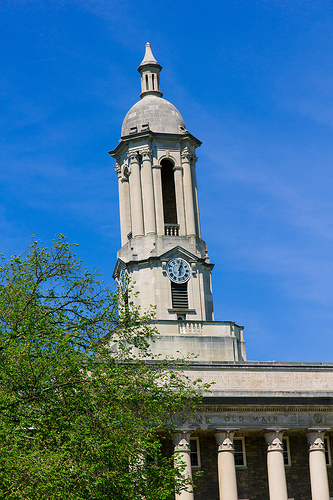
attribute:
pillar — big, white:
[116, 60, 216, 288]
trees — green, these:
[23, 266, 165, 451]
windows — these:
[232, 437, 255, 484]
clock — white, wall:
[172, 249, 197, 293]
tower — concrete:
[115, 71, 237, 368]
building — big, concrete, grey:
[104, 49, 312, 418]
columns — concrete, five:
[104, 140, 208, 242]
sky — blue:
[27, 24, 312, 191]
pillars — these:
[119, 153, 153, 229]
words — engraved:
[205, 413, 327, 433]